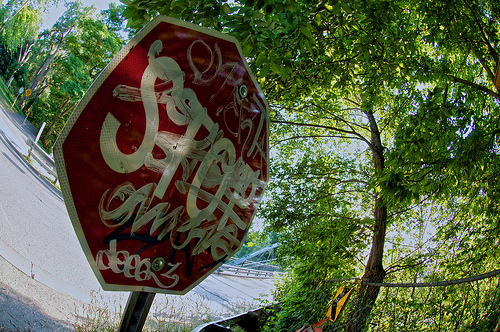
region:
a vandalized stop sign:
[56, 28, 284, 300]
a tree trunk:
[343, 245, 386, 330]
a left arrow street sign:
[326, 278, 350, 318]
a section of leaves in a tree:
[291, 18, 425, 92]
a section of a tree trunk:
[351, 256, 396, 328]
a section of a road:
[8, 174, 42, 235]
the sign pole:
[103, 300, 168, 330]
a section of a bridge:
[248, 246, 277, 275]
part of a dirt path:
[11, 287, 56, 326]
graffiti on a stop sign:
[97, 233, 180, 288]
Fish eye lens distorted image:
[8, 8, 491, 326]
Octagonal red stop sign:
[47, 13, 268, 296]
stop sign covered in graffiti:
[90, 41, 266, 289]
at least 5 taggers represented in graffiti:
[92, 47, 269, 285]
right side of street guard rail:
[178, 291, 285, 327]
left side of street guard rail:
[25, 140, 296, 280]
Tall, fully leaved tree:
[325, 44, 424, 328]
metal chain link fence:
[296, 254, 498, 326]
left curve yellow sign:
[308, 273, 360, 325]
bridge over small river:
[207, 239, 330, 324]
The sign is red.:
[45, 15, 276, 305]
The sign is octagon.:
[44, 10, 276, 304]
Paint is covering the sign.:
[47, 13, 279, 301]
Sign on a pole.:
[47, 7, 275, 329]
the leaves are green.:
[117, 11, 493, 329]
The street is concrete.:
[1, 97, 283, 330]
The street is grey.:
[1, 104, 268, 330]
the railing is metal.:
[21, 123, 62, 180]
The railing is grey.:
[20, 130, 57, 177]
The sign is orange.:
[314, 277, 354, 330]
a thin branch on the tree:
[387, 232, 465, 274]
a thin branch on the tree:
[301, 276, 359, 291]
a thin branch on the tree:
[269, 202, 369, 223]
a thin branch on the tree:
[282, 165, 366, 181]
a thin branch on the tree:
[275, 117, 372, 152]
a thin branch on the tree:
[393, 267, 477, 287]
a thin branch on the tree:
[311, 222, 369, 269]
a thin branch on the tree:
[408, 72, 498, 102]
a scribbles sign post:
[54, 10, 281, 294]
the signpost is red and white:
[52, 15, 269, 292]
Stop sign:
[51, 15, 271, 297]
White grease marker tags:
[97, 41, 264, 288]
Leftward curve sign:
[325, 278, 350, 326]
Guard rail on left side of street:
[16, 135, 56, 181]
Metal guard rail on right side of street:
[186, 292, 286, 327]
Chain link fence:
[286, 266, 496, 327]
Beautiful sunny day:
[243, 60, 494, 270]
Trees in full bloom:
[260, 17, 493, 327]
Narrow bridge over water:
[215, 261, 296, 311]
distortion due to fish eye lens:
[4, 20, 493, 330]